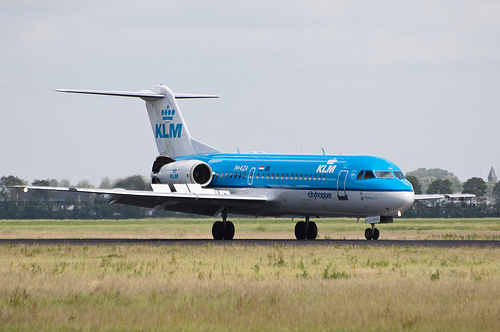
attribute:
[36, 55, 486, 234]
plane — blue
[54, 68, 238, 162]
tail — white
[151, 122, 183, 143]
klm — blue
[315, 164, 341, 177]
klm — white